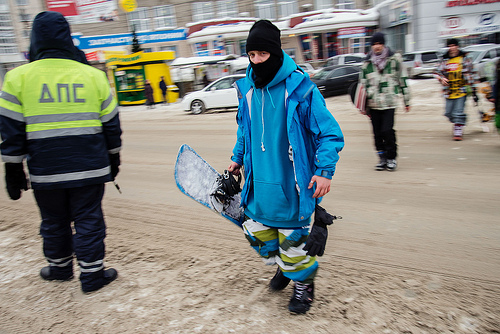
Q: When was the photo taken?
A: Daytime.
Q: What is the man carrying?
A: Snowboard.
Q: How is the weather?
A: Cold.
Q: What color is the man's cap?
A: Black.